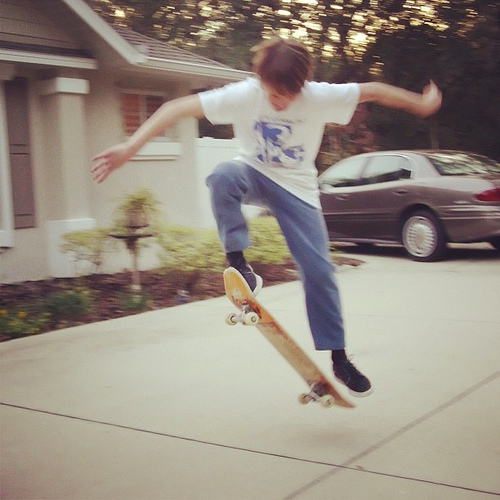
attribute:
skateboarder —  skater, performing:
[91, 40, 441, 408]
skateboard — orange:
[222, 267, 354, 412]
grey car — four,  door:
[318, 149, 499, 261]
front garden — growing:
[2, 259, 365, 343]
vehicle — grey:
[322, 156, 484, 252]